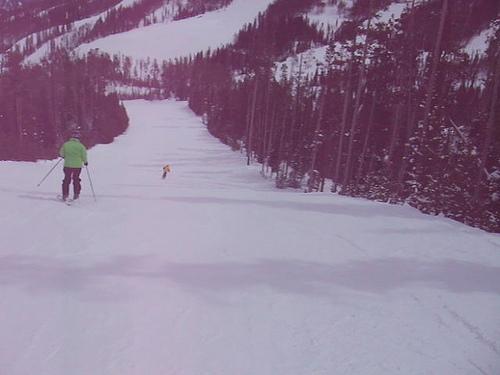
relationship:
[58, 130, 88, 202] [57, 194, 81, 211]
male holding ski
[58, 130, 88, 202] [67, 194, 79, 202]
male holding ski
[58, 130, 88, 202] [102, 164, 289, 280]
male on slope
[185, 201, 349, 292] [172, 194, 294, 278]
snow on ground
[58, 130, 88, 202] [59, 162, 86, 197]
male has on pants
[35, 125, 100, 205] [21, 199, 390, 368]
male snowboarding down hill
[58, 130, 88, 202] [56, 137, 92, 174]
male wearing jacket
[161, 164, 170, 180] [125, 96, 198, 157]
person going downhill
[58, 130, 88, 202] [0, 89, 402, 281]
male going downhill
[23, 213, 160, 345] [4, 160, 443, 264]
snow on ground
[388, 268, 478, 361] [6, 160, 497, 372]
snow on ground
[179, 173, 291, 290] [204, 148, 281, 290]
snow on ground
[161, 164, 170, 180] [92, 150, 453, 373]
person skiing down mountain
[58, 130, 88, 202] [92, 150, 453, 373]
male skiing down mountain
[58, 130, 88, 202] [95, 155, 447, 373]
male skiing down slope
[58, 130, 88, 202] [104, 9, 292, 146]
male going down mountain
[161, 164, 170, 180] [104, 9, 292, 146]
person going down mountain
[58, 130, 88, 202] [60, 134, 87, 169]
male wearing jacket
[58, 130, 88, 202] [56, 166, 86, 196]
male wearing pants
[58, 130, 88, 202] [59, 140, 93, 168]
male wearing jacket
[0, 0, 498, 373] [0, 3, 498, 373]
snow on mountain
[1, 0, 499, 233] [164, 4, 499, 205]
trees lining slope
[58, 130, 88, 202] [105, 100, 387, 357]
male skiing down slopes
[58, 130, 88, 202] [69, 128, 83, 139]
male wearing hat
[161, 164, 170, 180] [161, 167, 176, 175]
person wearing yellow jacket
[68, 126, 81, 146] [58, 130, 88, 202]
head on male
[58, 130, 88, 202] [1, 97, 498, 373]
male going down slope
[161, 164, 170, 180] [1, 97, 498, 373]
person going down slope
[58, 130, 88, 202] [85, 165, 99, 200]
male has stick